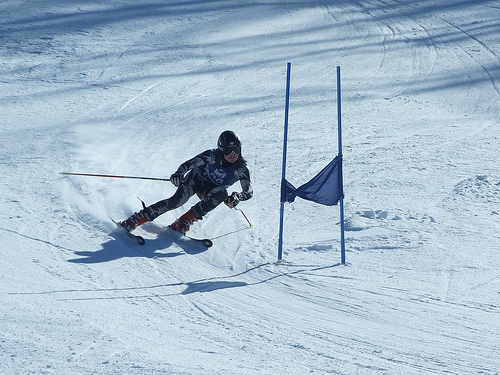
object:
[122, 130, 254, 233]
person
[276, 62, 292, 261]
slalom pole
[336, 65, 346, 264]
slalom pole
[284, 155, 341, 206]
flag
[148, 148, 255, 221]
suit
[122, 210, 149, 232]
boot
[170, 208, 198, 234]
boot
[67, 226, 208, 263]
shadow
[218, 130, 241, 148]
helmet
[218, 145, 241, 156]
goggles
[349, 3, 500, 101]
tracks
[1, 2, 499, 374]
snow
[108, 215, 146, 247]
skis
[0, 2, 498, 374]
slope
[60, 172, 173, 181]
ski pole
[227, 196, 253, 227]
ski pole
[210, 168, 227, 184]
writing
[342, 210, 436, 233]
snow pile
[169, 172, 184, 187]
glove